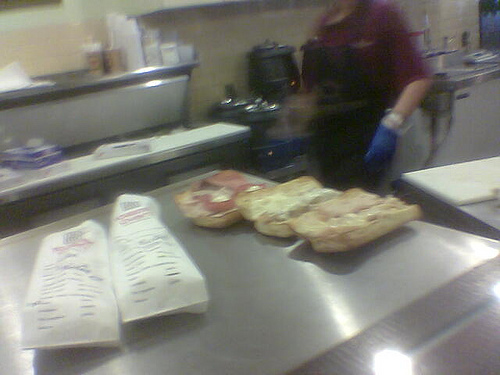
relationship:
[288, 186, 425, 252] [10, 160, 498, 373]
bread on counter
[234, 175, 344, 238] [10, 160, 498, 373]
bread on counter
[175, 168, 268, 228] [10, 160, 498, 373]
bread on counter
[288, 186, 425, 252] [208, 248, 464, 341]
bread on counter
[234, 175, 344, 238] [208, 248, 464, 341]
bread on counter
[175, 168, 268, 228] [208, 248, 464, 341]
bread on counter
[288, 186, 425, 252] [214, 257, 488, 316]
bread on table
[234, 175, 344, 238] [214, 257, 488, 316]
bread on table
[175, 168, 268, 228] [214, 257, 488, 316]
bread on table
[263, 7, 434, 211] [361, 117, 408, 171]
cook wears glove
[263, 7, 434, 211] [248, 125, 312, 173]
cook wears glove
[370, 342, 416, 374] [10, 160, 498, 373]
light reflects on counter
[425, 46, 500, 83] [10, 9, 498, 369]
sink in kitchen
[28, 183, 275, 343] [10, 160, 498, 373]
bag on counter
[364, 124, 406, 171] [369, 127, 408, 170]
glove on hand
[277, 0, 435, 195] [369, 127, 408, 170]
cook has hand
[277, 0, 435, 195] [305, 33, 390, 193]
cook in apron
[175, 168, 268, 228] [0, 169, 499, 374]
bread sitting on counter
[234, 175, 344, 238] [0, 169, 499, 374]
bread sitting on counter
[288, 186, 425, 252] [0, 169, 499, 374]
bread sitting on counter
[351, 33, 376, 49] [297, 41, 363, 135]
logo on shirt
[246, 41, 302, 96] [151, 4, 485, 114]
pot near wall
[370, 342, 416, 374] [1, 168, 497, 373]
light on surface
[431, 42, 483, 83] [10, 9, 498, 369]
sink in kitchen